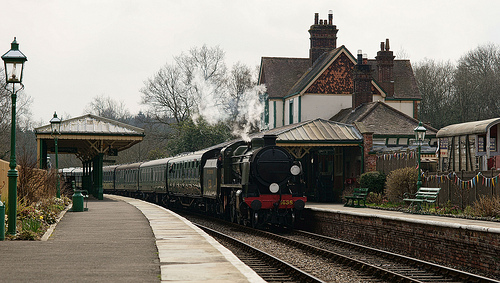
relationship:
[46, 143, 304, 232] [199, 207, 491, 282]
train on top of tracks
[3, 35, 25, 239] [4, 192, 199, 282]
street lamp on top of sidewalk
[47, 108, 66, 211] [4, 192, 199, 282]
street lamp on top of sidewalk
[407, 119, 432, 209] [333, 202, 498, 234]
street lamp on top of sidewalk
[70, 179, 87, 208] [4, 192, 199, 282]
bench on top of sidewalk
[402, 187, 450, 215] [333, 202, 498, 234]
bench on top of sidewalk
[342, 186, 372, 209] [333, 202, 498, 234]
bench on top of sidewalk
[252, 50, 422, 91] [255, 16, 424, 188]
roof on top of building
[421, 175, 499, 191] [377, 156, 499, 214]
flags draped in front of a fence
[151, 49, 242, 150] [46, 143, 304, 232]
tree behind train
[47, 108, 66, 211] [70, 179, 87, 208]
street lamp behind a bench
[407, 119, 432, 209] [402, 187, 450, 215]
street lamp behind a bench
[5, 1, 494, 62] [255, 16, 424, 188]
sky above building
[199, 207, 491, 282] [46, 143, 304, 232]
tracks are below train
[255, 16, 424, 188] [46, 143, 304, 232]
building behind train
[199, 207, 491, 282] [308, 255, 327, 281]
tracks are filled with gravel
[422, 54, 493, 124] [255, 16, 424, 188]
trees are behind building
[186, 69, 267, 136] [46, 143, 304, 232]
smoke above train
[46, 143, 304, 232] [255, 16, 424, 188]
train in front of building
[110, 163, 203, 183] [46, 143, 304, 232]
windows are on side of train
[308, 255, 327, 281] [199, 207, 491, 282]
gravel covers tracks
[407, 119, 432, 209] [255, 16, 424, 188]
street lamp in front of station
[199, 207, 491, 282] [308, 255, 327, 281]
tracks are on top of gravel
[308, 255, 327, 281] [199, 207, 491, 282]
gravel among tracks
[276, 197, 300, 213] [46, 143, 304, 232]
numbers printed on front of train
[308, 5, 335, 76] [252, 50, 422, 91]
chimney on top of roof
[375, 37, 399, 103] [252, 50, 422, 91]
chimney on top of roof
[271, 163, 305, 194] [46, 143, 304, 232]
headlights in front of train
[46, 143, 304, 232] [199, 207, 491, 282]
train sitting on top of tracks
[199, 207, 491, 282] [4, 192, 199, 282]
tracks to right of a sidewalk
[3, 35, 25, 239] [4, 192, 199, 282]
street lamp on top of a sidewalk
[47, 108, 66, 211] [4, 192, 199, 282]
street lamp on top of a sidewalk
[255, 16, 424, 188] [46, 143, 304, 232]
building to right of a train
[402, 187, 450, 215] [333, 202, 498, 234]
bench on top of a sidewalk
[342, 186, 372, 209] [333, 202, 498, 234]
bench on top of a sidewalk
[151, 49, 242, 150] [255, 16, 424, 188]
tree behind building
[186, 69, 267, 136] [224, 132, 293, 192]
smoke arises from engine